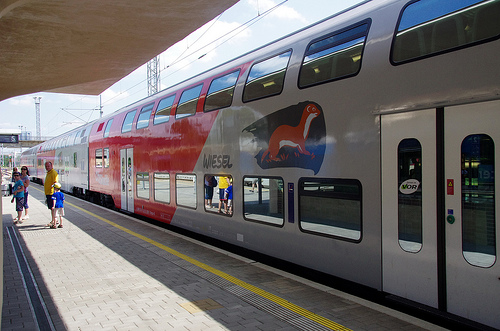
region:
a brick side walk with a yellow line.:
[96, 271, 312, 319]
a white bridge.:
[0, 127, 48, 151]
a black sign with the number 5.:
[0, 127, 34, 154]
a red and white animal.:
[257, 95, 337, 167]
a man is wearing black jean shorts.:
[12, 194, 25, 210]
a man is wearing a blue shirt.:
[11, 181, 27, 196]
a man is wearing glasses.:
[8, 169, 25, 182]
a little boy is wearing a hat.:
[48, 181, 70, 193]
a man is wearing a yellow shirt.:
[37, 157, 61, 189]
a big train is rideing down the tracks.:
[1, 0, 498, 329]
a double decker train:
[85, 0, 495, 323]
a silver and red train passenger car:
[89, 2, 497, 325]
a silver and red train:
[38, 117, 93, 196]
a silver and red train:
[13, 136, 34, 179]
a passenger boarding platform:
[2, 164, 439, 329]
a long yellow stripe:
[19, 180, 342, 327]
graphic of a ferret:
[253, 103, 322, 162]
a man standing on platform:
[39, 154, 58, 224]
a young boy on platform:
[46, 182, 64, 231]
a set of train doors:
[379, 108, 498, 327]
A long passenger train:
[19, 36, 498, 324]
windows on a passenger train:
[109, 0, 496, 132]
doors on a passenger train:
[366, 90, 495, 329]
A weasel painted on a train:
[241, 98, 327, 178]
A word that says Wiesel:
[198, 147, 237, 172]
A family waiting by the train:
[5, 148, 70, 225]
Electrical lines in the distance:
[20, 87, 116, 157]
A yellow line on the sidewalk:
[66, 195, 321, 330]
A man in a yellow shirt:
[37, 158, 62, 197]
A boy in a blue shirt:
[45, 180, 67, 214]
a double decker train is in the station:
[14, 8, 499, 321]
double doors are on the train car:
[380, 100, 499, 324]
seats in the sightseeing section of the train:
[301, 23, 493, 83]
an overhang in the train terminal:
[7, 13, 207, 163]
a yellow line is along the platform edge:
[24, 177, 379, 329]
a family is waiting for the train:
[9, 159, 75, 229]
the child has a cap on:
[46, 180, 69, 230]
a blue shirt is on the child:
[49, 190, 66, 210]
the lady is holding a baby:
[8, 160, 30, 188]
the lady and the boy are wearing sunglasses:
[8, 163, 30, 187]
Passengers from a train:
[7, 159, 65, 229]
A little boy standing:
[51, 181, 64, 230]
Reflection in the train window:
[205, 173, 233, 215]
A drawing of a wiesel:
[255, 99, 327, 171]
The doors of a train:
[376, 100, 499, 312]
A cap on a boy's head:
[51, 181, 62, 191]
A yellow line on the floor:
[178, 250, 209, 280]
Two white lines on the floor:
[17, 266, 42, 301]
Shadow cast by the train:
[159, 249, 221, 282]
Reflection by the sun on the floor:
[50, 246, 107, 293]